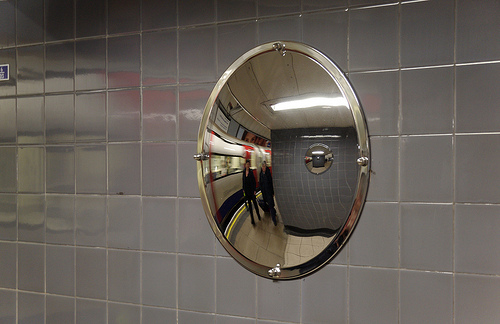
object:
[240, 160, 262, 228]
person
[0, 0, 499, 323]
wall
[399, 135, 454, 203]
tiles